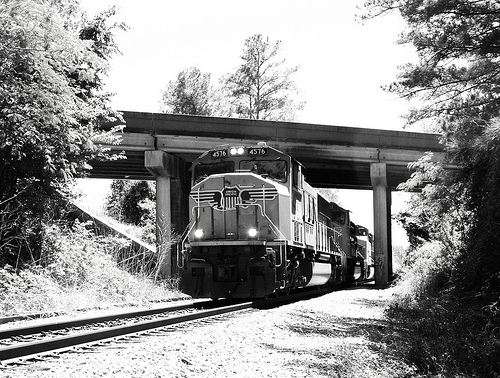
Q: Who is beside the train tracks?
A: No one.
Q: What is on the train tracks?
A: A train.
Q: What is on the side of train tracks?
A: Bushes.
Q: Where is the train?
A: On the train tracks.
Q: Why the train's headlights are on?
A: For safety.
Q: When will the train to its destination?
A: Later.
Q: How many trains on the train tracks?
A: One.